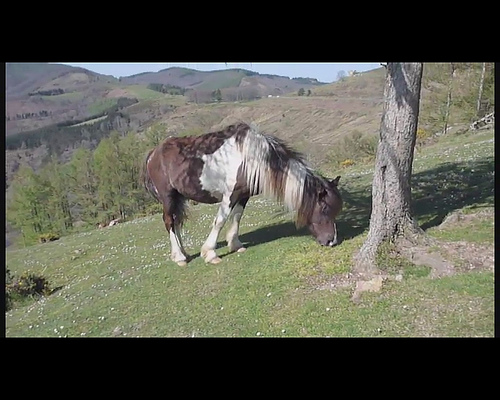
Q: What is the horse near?
A: The tree.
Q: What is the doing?
A: Eating.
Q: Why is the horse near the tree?
A: The horse is eating.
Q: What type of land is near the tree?
A: Green and barren.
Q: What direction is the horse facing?
A: Right.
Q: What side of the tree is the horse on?
A: Left.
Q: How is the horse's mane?
A: Long and thin.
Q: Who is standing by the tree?
A: Horse.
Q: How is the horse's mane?
A: Striped brown and white.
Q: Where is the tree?
A: On a hillside.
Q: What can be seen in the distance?
A: Hills.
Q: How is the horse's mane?
A: Long.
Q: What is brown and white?
A: Mane.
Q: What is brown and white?
A: Pony.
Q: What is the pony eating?
A: Green grass.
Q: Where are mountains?
A: In distance.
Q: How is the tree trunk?
A: Gray.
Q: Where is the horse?
A: By a tree.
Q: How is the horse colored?
A: Brown and white.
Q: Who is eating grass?
A: The horse.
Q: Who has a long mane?
A: The horse.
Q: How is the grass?
A: Green.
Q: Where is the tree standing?
A: On a hill.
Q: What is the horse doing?
A: Standing.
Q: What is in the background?
A: Hills.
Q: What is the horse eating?
A: Grass.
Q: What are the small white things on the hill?
A: Flowers.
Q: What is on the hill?
A: Trees.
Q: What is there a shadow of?
A: A tree.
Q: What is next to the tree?
A: A pony.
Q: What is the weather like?
A: Sunny.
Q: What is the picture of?
A: A horse.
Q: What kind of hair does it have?
A: Shaggy.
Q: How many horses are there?
A: One.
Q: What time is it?
A: Daytime.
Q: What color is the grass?
A: Green.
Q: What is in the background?
A: Trees and hills.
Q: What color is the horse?
A: Brown and white.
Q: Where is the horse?
A: Close to the tree.